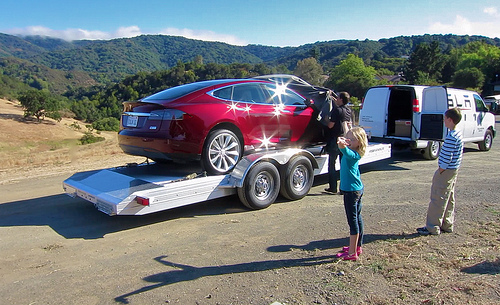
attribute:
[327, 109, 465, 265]
children — casting shadows, standing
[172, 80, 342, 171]
car side — shining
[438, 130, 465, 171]
shirt — striped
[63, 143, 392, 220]
trailer — long, white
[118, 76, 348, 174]
car — red, on the trailer, magenta, being covered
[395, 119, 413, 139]
cardboard box — in the van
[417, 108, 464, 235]
boy — young, standing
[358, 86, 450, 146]
back door — open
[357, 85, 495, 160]
truck — big, white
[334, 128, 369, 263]
girl — casting a shadow, standing, blonde, little, near the car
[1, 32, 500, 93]
hill — green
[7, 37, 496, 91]
trees — green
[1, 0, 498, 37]
sky — blue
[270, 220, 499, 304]
grass — brown, dead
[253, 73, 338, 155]
tarp — black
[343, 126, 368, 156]
hair — blonde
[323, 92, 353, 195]
man — standing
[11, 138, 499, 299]
road — dirty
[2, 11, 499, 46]
clouds — peeking